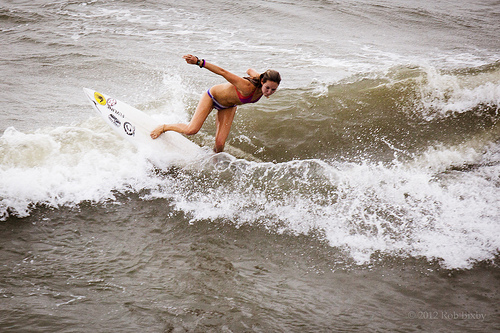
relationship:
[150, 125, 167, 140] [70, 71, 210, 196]
foot on a surfboard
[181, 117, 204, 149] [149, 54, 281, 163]
knee on a woman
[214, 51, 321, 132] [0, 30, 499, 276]
woman surfing wave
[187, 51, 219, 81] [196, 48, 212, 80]
wristbands on wrist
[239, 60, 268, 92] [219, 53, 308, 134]
arm of surfer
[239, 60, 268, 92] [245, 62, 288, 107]
arm visible behind head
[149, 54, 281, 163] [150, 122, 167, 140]
woman has foot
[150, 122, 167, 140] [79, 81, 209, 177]
foot on surfboard